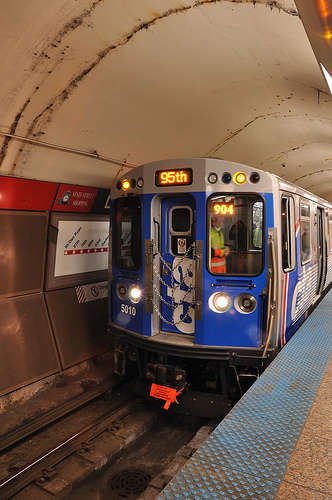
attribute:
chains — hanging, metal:
[152, 239, 196, 330]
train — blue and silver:
[99, 153, 331, 388]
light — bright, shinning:
[233, 166, 248, 184]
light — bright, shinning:
[119, 174, 133, 191]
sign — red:
[0, 172, 101, 215]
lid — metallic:
[106, 465, 150, 497]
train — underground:
[100, 149, 291, 331]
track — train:
[2, 365, 239, 478]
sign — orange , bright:
[144, 386, 183, 402]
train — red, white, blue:
[122, 152, 300, 330]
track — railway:
[51, 361, 198, 444]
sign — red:
[148, 382, 176, 400]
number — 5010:
[116, 301, 136, 319]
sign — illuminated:
[211, 203, 234, 215]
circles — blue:
[191, 418, 299, 482]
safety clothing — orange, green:
[206, 225, 228, 273]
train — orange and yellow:
[117, 159, 320, 332]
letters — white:
[166, 254, 197, 335]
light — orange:
[154, 168, 191, 186]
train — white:
[112, 156, 330, 414]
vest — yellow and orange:
[209, 225, 227, 271]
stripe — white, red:
[281, 271, 290, 344]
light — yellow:
[121, 165, 248, 187]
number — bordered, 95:
[153, 166, 189, 184]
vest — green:
[211, 229, 227, 251]